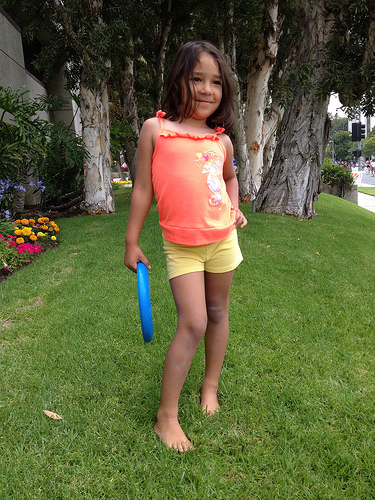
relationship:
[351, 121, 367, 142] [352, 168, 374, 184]
light over street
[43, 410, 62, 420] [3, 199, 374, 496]
leaf on top of grass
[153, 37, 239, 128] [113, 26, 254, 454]
head of a girl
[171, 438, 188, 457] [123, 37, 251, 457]
toe of a girl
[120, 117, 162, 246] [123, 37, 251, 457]
arm of a girl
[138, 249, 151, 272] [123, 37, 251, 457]
thumb of a girl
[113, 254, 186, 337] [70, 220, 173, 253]
frisbee in hand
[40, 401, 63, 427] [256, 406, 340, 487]
leaf on grass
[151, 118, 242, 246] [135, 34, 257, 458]
tank on girl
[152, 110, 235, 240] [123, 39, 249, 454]
shirt on girl